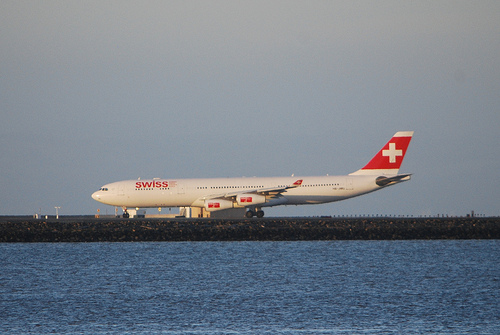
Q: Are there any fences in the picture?
A: No, there are no fences.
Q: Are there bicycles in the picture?
A: No, there are no bicycles.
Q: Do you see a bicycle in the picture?
A: No, there are no bicycles.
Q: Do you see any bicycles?
A: No, there are no bicycles.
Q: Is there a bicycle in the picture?
A: No, there are no bicycles.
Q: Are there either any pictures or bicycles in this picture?
A: No, there are no bicycles or pictures.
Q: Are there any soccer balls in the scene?
A: No, there are no soccer balls.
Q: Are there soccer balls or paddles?
A: No, there are no soccer balls or paddles.